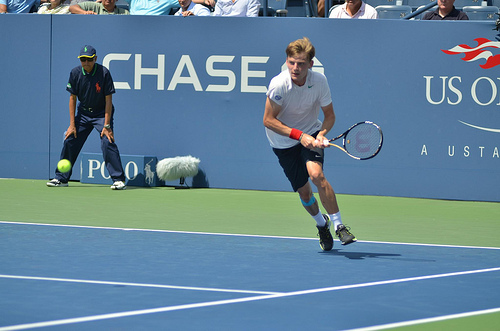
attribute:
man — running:
[260, 37, 360, 255]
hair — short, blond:
[283, 25, 313, 65]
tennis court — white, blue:
[2, 219, 484, 329]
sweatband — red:
[287, 128, 302, 140]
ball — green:
[50, 150, 77, 175]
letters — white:
[95, 39, 269, 100]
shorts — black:
[281, 139, 331, 191]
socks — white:
[317, 210, 340, 235]